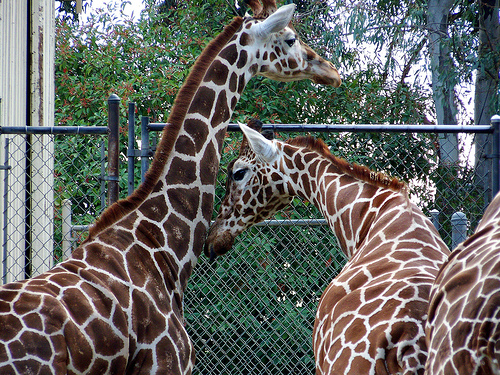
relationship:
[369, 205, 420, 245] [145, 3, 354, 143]
patch on giraffe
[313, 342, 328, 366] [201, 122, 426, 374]
patch on giraffe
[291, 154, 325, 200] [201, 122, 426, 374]
patch on giraffe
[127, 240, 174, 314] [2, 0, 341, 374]
patch on giraffe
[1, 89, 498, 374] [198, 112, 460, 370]
fence in front of giaffe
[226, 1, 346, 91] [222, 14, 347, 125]
head of giraffe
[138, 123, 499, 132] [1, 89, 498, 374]
bar on fence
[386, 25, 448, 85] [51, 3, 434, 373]
sky above trees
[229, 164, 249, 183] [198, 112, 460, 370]
eye of giaffe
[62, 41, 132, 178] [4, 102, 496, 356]
trees behind fence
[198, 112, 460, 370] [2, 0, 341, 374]
giaffe sniffing giraffe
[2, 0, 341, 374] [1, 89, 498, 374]
giraffe looking behind fence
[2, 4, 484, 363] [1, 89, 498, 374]
giraffes behind fence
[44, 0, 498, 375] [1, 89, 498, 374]
plants behind fence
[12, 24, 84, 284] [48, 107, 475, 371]
structure behind fence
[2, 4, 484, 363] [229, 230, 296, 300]
giraffes behind fence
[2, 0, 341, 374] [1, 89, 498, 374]
giraffe behind fence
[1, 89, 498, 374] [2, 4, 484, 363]
fence in front of giraffes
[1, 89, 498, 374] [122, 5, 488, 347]
fence in front of giaffe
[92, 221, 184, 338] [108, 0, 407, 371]
brown spots on giraffe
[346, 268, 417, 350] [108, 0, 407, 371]
brown spots on giraffe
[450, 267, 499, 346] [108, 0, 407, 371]
brown spots on giraffe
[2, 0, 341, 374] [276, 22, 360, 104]
giraffe has snout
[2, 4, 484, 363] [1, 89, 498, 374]
giraffes in fence